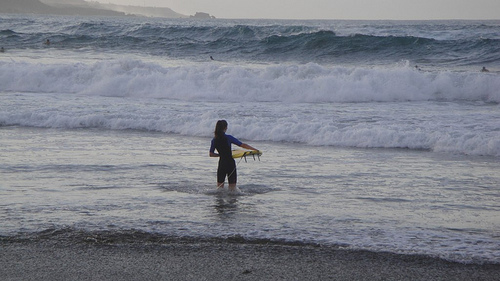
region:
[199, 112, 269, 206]
a surfer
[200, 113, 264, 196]
a woman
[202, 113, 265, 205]
a woman stands in the water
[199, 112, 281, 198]
the surfer stands in the water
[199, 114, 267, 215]
the woman is holding a surfboard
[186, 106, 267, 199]
the woman in the water carries a surfboard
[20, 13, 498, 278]
waves coming to shore in the ocean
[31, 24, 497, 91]
other surfers are in the water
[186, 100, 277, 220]
the woman is getting ready to surf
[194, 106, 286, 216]
the woman holds a yellow surfboard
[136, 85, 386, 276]
a woman standing in the water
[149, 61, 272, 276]
a woman holding a surfboard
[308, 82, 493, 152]
a body of water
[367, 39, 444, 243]
a body of wavy water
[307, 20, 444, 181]
a body of water with waves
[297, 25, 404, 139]
a clear body of water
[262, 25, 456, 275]
a body of clear water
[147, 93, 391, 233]
a surfer standing in the water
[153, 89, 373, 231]
a surfer with wetsuit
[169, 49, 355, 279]
a surfer holding surfboard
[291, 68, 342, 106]
large white waves crashing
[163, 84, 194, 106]
large white waves crashing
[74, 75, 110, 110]
large white waves crashing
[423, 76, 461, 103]
large white waves crashing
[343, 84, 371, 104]
large white waves crashing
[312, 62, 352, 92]
large white waves crashing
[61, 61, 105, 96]
large white waves crashing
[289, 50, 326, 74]
large white waves crashing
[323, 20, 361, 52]
large white waves crashing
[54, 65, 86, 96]
large white waves crashing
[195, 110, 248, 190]
surfer girl on her way out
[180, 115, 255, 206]
lady with surfboard ready to go in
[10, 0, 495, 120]
nice ocean waves off the shore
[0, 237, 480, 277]
sandy beach with waves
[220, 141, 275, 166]
yellow surfboard held by surfer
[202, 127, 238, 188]
black and blue wetsuit on the girl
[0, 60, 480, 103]
breaking waves into the shore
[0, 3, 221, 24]
rocky shoreline in the distance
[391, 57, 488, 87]
surfers out in the wave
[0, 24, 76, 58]
distant surfers in the water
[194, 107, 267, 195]
woman stand in the water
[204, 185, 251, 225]
reflection of woman on the water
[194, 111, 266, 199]
woman holding a yellow surfboard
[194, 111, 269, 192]
woman wears a black wetsuit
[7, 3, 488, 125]
many waves in the sea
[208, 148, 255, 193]
a rope hanging from surfboard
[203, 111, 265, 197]
woman wears a pony tail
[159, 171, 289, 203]
ripples are formed around person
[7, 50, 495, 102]
water of wave is foamy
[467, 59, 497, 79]
a person in the sea